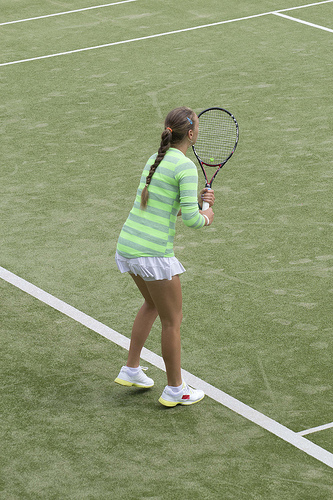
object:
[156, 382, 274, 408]
shoes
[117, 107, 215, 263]
top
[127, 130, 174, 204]
braid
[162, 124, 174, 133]
hairband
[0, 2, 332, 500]
court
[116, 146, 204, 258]
shirt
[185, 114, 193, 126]
hair pin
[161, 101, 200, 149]
head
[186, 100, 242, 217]
racket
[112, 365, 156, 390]
shoe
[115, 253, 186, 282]
shorts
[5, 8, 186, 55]
lines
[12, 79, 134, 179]
ground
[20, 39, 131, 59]
white line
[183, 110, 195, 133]
barrette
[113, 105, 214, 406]
player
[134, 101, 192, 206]
hair